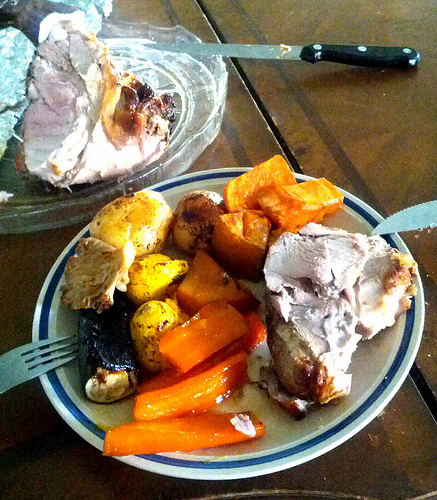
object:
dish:
[33, 165, 425, 483]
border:
[391, 349, 409, 372]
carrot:
[158, 301, 254, 372]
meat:
[269, 223, 414, 409]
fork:
[0, 332, 86, 394]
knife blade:
[146, 38, 304, 60]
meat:
[20, 31, 174, 195]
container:
[0, 8, 229, 213]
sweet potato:
[258, 178, 353, 230]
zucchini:
[78, 305, 138, 400]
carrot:
[135, 349, 251, 420]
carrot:
[103, 408, 268, 457]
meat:
[231, 415, 263, 441]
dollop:
[132, 255, 191, 304]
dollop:
[127, 299, 193, 367]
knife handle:
[304, 41, 420, 69]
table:
[6, 3, 435, 488]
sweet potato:
[218, 211, 269, 274]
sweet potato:
[227, 153, 300, 208]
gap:
[238, 70, 291, 144]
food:
[62, 238, 123, 309]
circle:
[313, 41, 323, 53]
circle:
[356, 45, 367, 53]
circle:
[403, 48, 409, 55]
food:
[92, 192, 170, 252]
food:
[279, 41, 291, 55]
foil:
[1, 23, 41, 158]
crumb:
[428, 351, 433, 363]